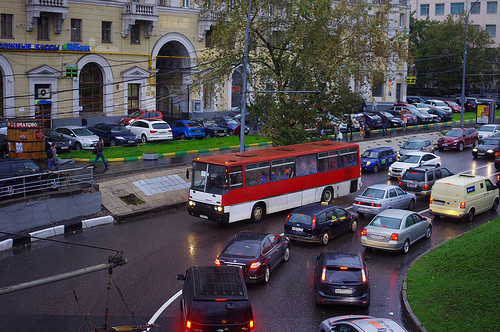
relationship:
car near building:
[57, 125, 102, 151] [27, 0, 411, 105]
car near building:
[127, 117, 171, 142] [27, 0, 411, 105]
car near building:
[169, 117, 204, 141] [27, 0, 411, 105]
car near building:
[362, 109, 383, 124] [27, 0, 411, 105]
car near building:
[92, 122, 137, 145] [27, 0, 411, 105]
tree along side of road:
[180, 1, 413, 146] [2, 147, 484, 329]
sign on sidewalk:
[473, 102, 490, 128] [399, 114, 499, 131]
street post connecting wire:
[236, 2, 258, 149] [0, 32, 242, 88]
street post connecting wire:
[236, 2, 258, 149] [3, 47, 245, 108]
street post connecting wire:
[236, 2, 258, 149] [5, 54, 245, 118]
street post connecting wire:
[236, 2, 258, 149] [28, 59, 244, 123]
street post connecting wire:
[236, 2, 258, 149] [254, 32, 463, 65]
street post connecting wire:
[455, 8, 472, 120] [0, 32, 242, 88]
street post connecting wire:
[455, 8, 472, 120] [3, 47, 245, 108]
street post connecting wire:
[455, 8, 472, 120] [5, 54, 245, 118]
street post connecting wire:
[455, 8, 472, 120] [28, 59, 244, 123]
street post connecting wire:
[455, 8, 472, 120] [254, 32, 463, 65]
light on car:
[249, 261, 261, 268] [214, 230, 290, 284]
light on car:
[214, 257, 221, 264] [214, 230, 290, 284]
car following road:
[312, 250, 386, 310] [25, 124, 479, 316]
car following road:
[210, 216, 301, 285] [25, 124, 479, 316]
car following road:
[362, 204, 449, 254] [25, 124, 479, 316]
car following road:
[282, 198, 361, 248] [25, 124, 479, 316]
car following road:
[349, 175, 417, 220] [25, 124, 479, 316]